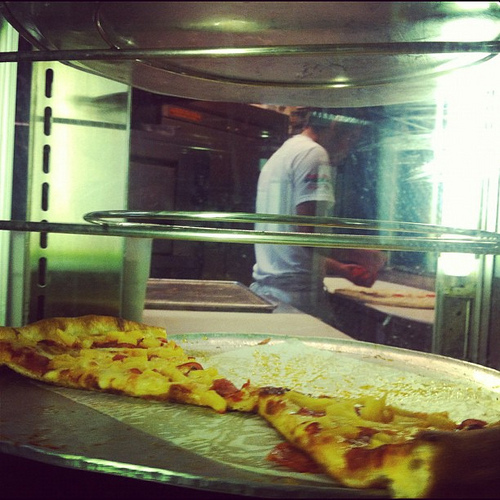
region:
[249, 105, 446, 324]
A Man making pizza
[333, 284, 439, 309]
Pizza dough on the counter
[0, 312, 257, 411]
A large slice of pizza on a tray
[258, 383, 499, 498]
Another large slice of pizza on a tray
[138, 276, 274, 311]
A silver empty tray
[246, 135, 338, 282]
The mans white shirt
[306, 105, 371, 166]
The man is looking down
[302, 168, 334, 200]
A colorful image on the mans shirt sleeve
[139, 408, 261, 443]
Greasy paper underneath the pizza slices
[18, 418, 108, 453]
Spots of sauce on the pizza tray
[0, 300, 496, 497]
two slices of pizza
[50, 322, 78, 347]
a piece of chunk pineapple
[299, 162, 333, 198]
a red and green logo on a shirt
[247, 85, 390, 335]
a man making some pizza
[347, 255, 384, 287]
a handful of pepperonis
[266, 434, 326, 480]
one slice of pepperoni underneath a piece of pizza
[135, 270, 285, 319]
a silver oven pan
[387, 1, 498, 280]
light reflecting into the camera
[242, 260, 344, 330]
a white, tied apron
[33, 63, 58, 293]
six vertical slots on the side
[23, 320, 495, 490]
pizzas are traingle in shape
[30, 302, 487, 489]
pizzas are on mettalic tray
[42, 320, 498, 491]
two pieces of pizza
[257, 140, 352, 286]
the shirt is white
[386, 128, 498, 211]
the light is bright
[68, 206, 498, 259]
the metal is silver in grey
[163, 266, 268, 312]
the tray is mettalic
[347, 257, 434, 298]
red toppings on the pizza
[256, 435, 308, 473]
bacon below the pizza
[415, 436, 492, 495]
brown crust on the pizza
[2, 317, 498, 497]
the pizza is almost gone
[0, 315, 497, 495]
the pizza has a topping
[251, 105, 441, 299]
the man makes pizza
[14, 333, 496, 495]
the pizza is on a metal plate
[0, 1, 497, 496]
this is a pizzeria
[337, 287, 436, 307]
the pizza is almost ready for the oven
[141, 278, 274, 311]
a metal tray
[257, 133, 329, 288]
man wears a tshirt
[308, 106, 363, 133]
the man has short hair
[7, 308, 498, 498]
Two slices of pizza on aluminum pan.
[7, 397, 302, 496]
Edge of aluminum pan.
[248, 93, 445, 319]
Man making a pizza.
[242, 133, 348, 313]
Man wearing white shirt.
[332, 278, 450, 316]
Pizza dough on counter.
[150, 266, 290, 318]
Square baking pan sitting on counter.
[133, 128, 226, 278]
A black pizza oven.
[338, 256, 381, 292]
Man holding slices of pepperoni.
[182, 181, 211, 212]
Control knob for pizza oven.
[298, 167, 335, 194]
Colored design on sleeve of white shirt.